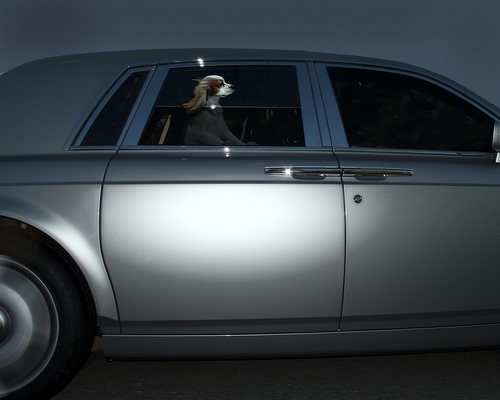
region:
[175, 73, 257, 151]
dog hanging head out car window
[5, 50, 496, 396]
silver four door car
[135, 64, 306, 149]
window cracked halfway open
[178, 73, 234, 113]
brown and white dog head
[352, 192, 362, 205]
gray door lock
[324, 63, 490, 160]
window tinted dark grey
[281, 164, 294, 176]
reflection of light in chrome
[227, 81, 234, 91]
small black nose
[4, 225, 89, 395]
black rubber of tire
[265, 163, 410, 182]
chrome car door handles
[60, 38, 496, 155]
dog riding in gray car in back seat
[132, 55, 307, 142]
dog with head partially out of lowered window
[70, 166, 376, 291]
light hitting top part of rear door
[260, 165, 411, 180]
line over recesses for oval handles in doors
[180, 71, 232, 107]
brown and white head with long hair in back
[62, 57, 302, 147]
narrow window panel behind main window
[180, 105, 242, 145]
legs slanted against bottom of window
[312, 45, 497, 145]
curve over front end of car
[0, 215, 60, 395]
silver and grey rings around center of wheel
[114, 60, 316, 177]
dog looking forward from back of the car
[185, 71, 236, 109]
white and brown dog with head out of window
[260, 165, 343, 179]
silver handle of rear door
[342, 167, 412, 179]
silver handle of front door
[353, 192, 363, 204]
silver lock of front door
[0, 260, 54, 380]
grey wheel in motion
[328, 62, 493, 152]
tinted window of grey car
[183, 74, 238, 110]
brown and white dog with fluffy ears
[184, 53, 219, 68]
reflection of camera on grey car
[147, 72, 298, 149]
window rolled down for dog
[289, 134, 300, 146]
metal door lock inside car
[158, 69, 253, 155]
dog in a car window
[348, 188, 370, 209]
key opening on car door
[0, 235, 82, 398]
wheel of a car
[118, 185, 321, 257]
shining light on a car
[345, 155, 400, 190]
handle on a front car door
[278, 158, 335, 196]
handle on a back car door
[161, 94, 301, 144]
opened window of a car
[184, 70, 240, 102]
head of a dog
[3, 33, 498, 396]
silver car on the road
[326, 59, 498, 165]
side window on a car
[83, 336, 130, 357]
part of a wheel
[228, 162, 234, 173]
edge of a window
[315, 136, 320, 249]
part of a door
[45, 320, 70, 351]
edge of a wheel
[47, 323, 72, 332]
part of a plate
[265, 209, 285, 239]
edge of a door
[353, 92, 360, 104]
edge of a window